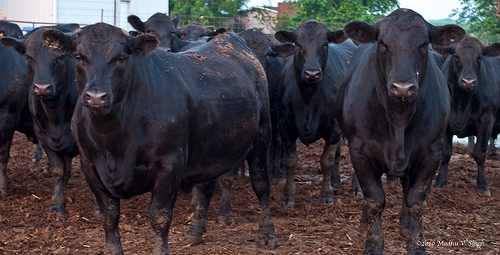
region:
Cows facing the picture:
[1, 3, 495, 249]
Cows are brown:
[1, 8, 498, 253]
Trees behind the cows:
[172, 0, 497, 30]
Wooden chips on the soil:
[8, 152, 493, 252]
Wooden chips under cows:
[9, 138, 497, 253]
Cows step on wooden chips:
[13, 151, 493, 251]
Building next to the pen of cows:
[2, 0, 169, 28]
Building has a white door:
[5, 0, 55, 23]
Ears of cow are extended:
[326, 7, 476, 52]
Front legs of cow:
[357, 162, 437, 253]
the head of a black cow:
[345, 2, 465, 104]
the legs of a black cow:
[355, 147, 437, 252]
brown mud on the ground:
[275, 200, 367, 252]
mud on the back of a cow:
[180, 40, 267, 89]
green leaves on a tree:
[293, 0, 379, 22]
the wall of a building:
[1, 0, 169, 22]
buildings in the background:
[243, 2, 294, 31]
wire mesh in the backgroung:
[176, 15, 249, 30]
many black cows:
[10, 11, 497, 248]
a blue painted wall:
[56, 0, 98, 23]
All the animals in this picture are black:
[16, 18, 496, 222]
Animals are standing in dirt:
[23, 160, 487, 252]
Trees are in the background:
[181, 0, 493, 42]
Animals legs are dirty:
[130, 147, 497, 253]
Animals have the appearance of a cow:
[36, 22, 491, 192]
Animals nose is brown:
[387, 74, 418, 101]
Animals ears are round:
[43, 15, 167, 67]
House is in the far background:
[233, 1, 289, 40]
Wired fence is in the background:
[48, 5, 293, 38]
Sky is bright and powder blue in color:
[393, 1, 462, 16]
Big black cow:
[342, 7, 464, 253]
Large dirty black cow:
[44, 23, 276, 253]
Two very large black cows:
[3, 19, 271, 254]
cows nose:
[390, 75, 418, 100]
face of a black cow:
[273, 19, 348, 82]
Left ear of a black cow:
[127, 29, 159, 59]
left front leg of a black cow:
[146, 159, 183, 254]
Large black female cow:
[42, 24, 274, 252]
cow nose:
[388, 77, 415, 97]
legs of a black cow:
[344, 135, 444, 254]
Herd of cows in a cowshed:
[0, 5, 499, 245]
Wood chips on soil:
[0, 147, 498, 254]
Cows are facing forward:
[0, 7, 497, 242]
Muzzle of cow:
[82, 98, 115, 112]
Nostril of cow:
[79, 86, 114, 102]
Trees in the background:
[174, 0, 499, 27]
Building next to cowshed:
[1, 1, 176, 22]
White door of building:
[0, 0, 55, 26]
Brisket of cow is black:
[95, 153, 142, 205]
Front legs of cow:
[86, 177, 178, 254]